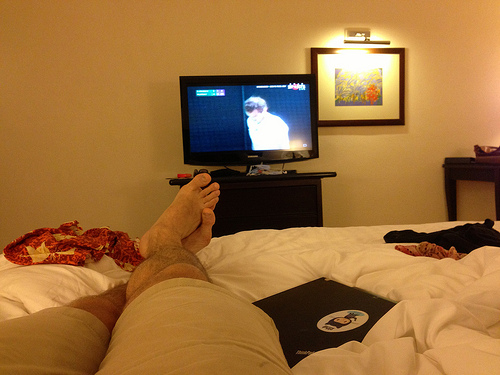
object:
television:
[177, 74, 318, 172]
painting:
[312, 47, 408, 126]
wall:
[0, 1, 499, 243]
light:
[343, 25, 372, 41]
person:
[1, 173, 292, 372]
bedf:
[2, 217, 497, 374]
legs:
[0, 173, 275, 373]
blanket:
[0, 221, 498, 372]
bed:
[0, 221, 498, 373]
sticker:
[316, 308, 369, 332]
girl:
[328, 311, 363, 329]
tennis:
[187, 85, 310, 151]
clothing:
[0, 217, 139, 274]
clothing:
[383, 218, 499, 257]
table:
[440, 156, 499, 221]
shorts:
[0, 279, 286, 371]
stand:
[167, 171, 337, 238]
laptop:
[249, 271, 400, 367]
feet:
[137, 171, 220, 260]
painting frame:
[310, 47, 406, 126]